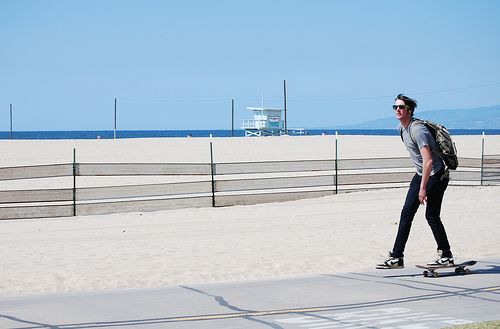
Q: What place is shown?
A: It is a beach.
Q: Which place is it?
A: It is a beach.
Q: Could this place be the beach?
A: Yes, it is the beach.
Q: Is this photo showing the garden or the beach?
A: It is showing the beach.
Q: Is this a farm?
A: No, it is a beach.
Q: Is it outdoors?
A: Yes, it is outdoors.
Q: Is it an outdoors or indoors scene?
A: It is outdoors.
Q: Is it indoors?
A: No, it is outdoors.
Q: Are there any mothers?
A: No, there are no mothers.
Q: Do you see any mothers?
A: No, there are no mothers.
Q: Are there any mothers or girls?
A: No, there are no mothers or girls.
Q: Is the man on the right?
A: Yes, the man is on the right of the image.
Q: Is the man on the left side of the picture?
A: No, the man is on the right of the image.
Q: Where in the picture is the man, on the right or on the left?
A: The man is on the right of the image.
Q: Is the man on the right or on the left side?
A: The man is on the right of the image.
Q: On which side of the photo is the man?
A: The man is on the right of the image.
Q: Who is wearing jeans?
A: The man is wearing jeans.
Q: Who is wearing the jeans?
A: The man is wearing jeans.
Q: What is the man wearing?
A: The man is wearing jeans.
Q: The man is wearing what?
A: The man is wearing jeans.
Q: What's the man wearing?
A: The man is wearing jeans.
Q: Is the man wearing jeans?
A: Yes, the man is wearing jeans.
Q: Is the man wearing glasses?
A: No, the man is wearing jeans.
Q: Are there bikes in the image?
A: Yes, there is a bike.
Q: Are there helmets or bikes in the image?
A: Yes, there is a bike.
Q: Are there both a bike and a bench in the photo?
A: No, there is a bike but no benches.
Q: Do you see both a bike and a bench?
A: No, there is a bike but no benches.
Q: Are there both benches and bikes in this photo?
A: No, there is a bike but no benches.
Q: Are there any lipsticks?
A: No, there are no lipsticks.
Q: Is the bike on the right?
A: Yes, the bike is on the right of the image.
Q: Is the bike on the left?
A: No, the bike is on the right of the image.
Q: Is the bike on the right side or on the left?
A: The bike is on the right of the image.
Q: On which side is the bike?
A: The bike is on the right of the image.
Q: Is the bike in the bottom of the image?
A: Yes, the bike is in the bottom of the image.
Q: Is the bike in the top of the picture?
A: No, the bike is in the bottom of the image.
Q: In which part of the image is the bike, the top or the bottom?
A: The bike is in the bottom of the image.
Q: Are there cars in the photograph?
A: No, there are no cars.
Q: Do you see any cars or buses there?
A: No, there are no cars or buses.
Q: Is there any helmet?
A: No, there are no helmets.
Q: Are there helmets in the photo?
A: No, there are no helmets.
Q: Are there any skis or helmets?
A: No, there are no helmets or skis.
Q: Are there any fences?
A: Yes, there is a fence.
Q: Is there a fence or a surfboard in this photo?
A: Yes, there is a fence.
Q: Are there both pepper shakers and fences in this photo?
A: No, there is a fence but no pepper shakers.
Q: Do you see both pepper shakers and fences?
A: No, there is a fence but no pepper shakers.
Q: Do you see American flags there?
A: No, there are no American flags.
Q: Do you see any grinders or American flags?
A: No, there are no American flags or grinders.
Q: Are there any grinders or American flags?
A: No, there are no American flags or grinders.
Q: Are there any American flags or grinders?
A: No, there are no American flags or grinders.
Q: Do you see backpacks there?
A: Yes, there is a backpack.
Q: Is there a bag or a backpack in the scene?
A: Yes, there is a backpack.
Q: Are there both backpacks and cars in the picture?
A: No, there is a backpack but no cars.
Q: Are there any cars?
A: No, there are no cars.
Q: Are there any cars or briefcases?
A: No, there are no cars or briefcases.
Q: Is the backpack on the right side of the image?
A: Yes, the backpack is on the right of the image.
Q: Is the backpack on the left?
A: No, the backpack is on the right of the image.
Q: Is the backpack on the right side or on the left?
A: The backpack is on the right of the image.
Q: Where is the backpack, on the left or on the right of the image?
A: The backpack is on the right of the image.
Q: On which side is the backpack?
A: The backpack is on the right of the image.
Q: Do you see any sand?
A: Yes, there is sand.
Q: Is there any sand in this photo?
A: Yes, there is sand.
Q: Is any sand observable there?
A: Yes, there is sand.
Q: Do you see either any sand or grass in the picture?
A: Yes, there is sand.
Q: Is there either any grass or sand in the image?
A: Yes, there is sand.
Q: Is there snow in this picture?
A: No, there is no snow.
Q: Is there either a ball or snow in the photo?
A: No, there are no snow or balls.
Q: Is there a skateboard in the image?
A: Yes, there is a skateboard.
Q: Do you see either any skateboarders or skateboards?
A: Yes, there is a skateboard.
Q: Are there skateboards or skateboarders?
A: Yes, there is a skateboard.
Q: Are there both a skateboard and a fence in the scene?
A: Yes, there are both a skateboard and a fence.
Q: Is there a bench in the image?
A: No, there are no benches.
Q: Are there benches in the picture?
A: No, there are no benches.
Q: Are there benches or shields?
A: No, there are no benches or shields.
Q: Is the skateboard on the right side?
A: Yes, the skateboard is on the right of the image.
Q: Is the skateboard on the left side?
A: No, the skateboard is on the right of the image.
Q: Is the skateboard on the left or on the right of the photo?
A: The skateboard is on the right of the image.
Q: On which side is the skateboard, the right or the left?
A: The skateboard is on the right of the image.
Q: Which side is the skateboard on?
A: The skateboard is on the right of the image.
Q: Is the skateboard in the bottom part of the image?
A: Yes, the skateboard is in the bottom of the image.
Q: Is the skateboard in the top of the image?
A: No, the skateboard is in the bottom of the image.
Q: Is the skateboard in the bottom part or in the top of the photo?
A: The skateboard is in the bottom of the image.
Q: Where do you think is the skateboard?
A: The skateboard is on the roadway.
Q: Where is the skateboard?
A: The skateboard is on the roadway.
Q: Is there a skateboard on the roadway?
A: Yes, there is a skateboard on the roadway.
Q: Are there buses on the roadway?
A: No, there is a skateboard on the roadway.